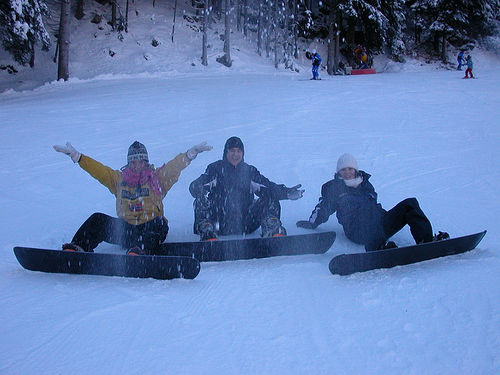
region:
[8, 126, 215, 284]
The woman is sitting in the snow.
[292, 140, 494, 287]
The woman is sitting in the snow.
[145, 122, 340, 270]
The man is sitting in the snow.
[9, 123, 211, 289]
The woman is wearing a cap.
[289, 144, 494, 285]
The woman is wearing a cap.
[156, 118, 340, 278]
The man is wearing a cap.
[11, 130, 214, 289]
The woman is wearing gloves.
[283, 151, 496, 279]
The woman is wearing gloves.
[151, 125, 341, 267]
The man is wearing gloves.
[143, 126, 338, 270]
The man is on a snowboard.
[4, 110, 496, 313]
Three snowboarders sitting in the snow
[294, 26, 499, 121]
People playing in the snow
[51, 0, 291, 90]
Snow falling on the ground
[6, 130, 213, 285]
Girl wearing yellow sweatshirt sitting in snow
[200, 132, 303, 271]
Boy sitting in snow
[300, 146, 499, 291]
Girl laying in snow with snowboard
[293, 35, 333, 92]
Person on snowboard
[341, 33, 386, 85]
People on innerturbe in the snow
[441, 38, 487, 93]
People snowboardin in snow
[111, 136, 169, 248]
Girl sitting in snow and smiling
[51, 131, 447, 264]
three snowboarders on the ground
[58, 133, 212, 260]
snowboarder wearing yellow jacket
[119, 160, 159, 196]
fuchsia scarf of snowboarder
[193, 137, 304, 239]
snowboarder wearing black balaclava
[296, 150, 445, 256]
snowboarder wearing white balaclava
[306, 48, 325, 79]
snowboarder on blue uniform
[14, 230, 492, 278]
three black snowboards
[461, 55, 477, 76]
snowboarder wearing red pants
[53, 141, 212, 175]
white gloves of snowboarder in the left side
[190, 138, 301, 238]
snowboarder in black suit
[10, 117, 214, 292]
The woman is wearing a snowboard.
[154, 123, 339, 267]
The man is wearing a snowboard.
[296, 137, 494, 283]
The woman is wearing a snowboard.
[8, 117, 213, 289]
The woman has her arms raised.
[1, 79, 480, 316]
three people in the snow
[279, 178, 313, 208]
hand of the person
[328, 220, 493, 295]
board under the person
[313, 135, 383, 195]
head of the person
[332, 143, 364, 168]
hat on person's head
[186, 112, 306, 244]
man in the middle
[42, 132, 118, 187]
arm of the man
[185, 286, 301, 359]
snow on the ground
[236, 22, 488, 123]
people in the background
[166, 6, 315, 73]
trees in the distance